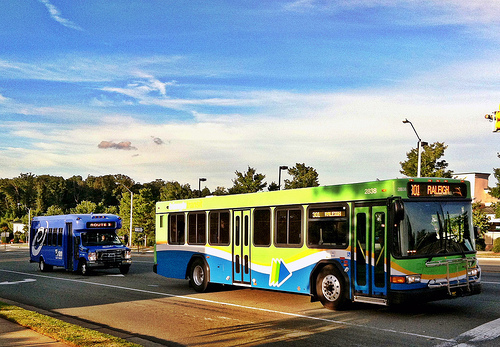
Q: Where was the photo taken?
A: It was taken at the street.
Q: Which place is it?
A: It is a street.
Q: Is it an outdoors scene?
A: Yes, it is outdoors.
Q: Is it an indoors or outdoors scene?
A: It is outdoors.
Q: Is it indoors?
A: No, it is outdoors.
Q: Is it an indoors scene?
A: No, it is outdoors.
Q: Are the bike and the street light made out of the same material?
A: Yes, both the bike and the street light are made of metal.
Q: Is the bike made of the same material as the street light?
A: Yes, both the bike and the street light are made of metal.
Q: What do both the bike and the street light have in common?
A: The material, both the bike and the street light are metallic.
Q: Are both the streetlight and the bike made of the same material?
A: Yes, both the streetlight and the bike are made of metal.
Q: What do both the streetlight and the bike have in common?
A: The material, both the streetlight and the bike are metallic.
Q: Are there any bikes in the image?
A: Yes, there is a bike.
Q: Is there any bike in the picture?
A: Yes, there is a bike.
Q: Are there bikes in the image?
A: Yes, there is a bike.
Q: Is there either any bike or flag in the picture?
A: Yes, there is a bike.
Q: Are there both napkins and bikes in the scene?
A: No, there is a bike but no napkins.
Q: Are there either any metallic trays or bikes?
A: Yes, there is a metal bike.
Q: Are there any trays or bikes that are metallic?
A: Yes, the bike is metallic.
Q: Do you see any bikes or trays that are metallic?
A: Yes, the bike is metallic.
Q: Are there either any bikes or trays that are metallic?
A: Yes, the bike is metallic.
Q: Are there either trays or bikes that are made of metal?
A: Yes, the bike is made of metal.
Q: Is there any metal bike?
A: Yes, there is a bike that is made of metal.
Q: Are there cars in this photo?
A: No, there are no cars.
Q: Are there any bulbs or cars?
A: No, there are no cars or bulbs.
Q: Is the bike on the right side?
A: Yes, the bike is on the right of the image.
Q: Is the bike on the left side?
A: No, the bike is on the right of the image.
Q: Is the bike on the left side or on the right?
A: The bike is on the right of the image.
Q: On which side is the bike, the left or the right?
A: The bike is on the right of the image.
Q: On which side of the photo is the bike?
A: The bike is on the right of the image.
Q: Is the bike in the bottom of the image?
A: Yes, the bike is in the bottom of the image.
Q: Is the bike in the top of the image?
A: No, the bike is in the bottom of the image.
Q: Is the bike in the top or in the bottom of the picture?
A: The bike is in the bottom of the image.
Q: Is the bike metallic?
A: Yes, the bike is metallic.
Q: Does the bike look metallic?
A: Yes, the bike is metallic.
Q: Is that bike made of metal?
A: Yes, the bike is made of metal.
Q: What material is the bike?
A: The bike is made of metal.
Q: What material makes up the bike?
A: The bike is made of metal.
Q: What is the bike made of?
A: The bike is made of metal.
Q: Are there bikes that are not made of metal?
A: No, there is a bike but it is made of metal.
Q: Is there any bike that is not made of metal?
A: No, there is a bike but it is made of metal.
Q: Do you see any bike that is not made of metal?
A: No, there is a bike but it is made of metal.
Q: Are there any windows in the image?
A: Yes, there is a window.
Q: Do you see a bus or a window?
A: Yes, there is a window.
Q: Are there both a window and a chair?
A: No, there is a window but no chairs.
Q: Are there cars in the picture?
A: No, there are no cars.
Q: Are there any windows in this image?
A: Yes, there is a window.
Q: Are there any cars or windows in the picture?
A: Yes, there is a window.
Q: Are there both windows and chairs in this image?
A: No, there is a window but no chairs.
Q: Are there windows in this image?
A: Yes, there is a window.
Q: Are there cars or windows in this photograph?
A: Yes, there is a window.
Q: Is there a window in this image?
A: Yes, there is a window.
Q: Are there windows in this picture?
A: Yes, there is a window.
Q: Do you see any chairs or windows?
A: Yes, there is a window.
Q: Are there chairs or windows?
A: Yes, there is a window.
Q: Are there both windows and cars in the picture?
A: No, there is a window but no cars.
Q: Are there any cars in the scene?
A: No, there are no cars.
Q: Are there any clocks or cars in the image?
A: No, there are no cars or clocks.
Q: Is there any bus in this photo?
A: Yes, there is a bus.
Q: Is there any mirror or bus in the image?
A: Yes, there is a bus.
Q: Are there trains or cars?
A: No, there are no cars or trains.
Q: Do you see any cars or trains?
A: No, there are no cars or trains.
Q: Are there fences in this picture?
A: No, there are no fences.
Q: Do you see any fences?
A: No, there are no fences.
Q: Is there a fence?
A: No, there are no fences.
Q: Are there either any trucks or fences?
A: No, there are no fences or trucks.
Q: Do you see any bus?
A: Yes, there is a bus.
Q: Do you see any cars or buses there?
A: Yes, there is a bus.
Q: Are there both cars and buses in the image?
A: No, there is a bus but no cars.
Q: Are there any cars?
A: No, there are no cars.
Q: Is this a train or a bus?
A: This is a bus.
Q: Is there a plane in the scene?
A: No, there are no airplanes.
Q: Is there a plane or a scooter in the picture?
A: No, there are no airplanes or scooters.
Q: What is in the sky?
A: The clouds are in the sky.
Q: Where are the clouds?
A: The clouds are in the sky.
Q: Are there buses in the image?
A: Yes, there is a bus.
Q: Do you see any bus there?
A: Yes, there is a bus.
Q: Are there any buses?
A: Yes, there is a bus.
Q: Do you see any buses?
A: Yes, there is a bus.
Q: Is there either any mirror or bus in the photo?
A: Yes, there is a bus.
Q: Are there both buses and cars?
A: No, there is a bus but no cars.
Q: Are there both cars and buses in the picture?
A: No, there is a bus but no cars.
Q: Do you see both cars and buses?
A: No, there is a bus but no cars.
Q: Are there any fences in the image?
A: No, there are no fences.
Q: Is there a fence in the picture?
A: No, there are no fences.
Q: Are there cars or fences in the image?
A: No, there are no fences or cars.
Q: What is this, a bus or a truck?
A: This is a bus.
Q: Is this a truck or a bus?
A: This is a bus.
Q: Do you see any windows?
A: Yes, there is a window.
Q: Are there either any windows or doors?
A: Yes, there is a window.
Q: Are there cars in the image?
A: No, there are no cars.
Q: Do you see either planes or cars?
A: No, there are no cars or planes.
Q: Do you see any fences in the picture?
A: No, there are no fences.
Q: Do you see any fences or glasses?
A: No, there are no fences or glasses.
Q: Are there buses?
A: Yes, there is a bus.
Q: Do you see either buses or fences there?
A: Yes, there is a bus.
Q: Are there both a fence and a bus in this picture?
A: No, there is a bus but no fences.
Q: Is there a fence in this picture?
A: No, there are no fences.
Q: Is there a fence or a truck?
A: No, there are no fences or trucks.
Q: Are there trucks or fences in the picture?
A: No, there are no fences or trucks.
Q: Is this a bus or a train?
A: This is a bus.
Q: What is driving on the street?
A: The bus is driving on the street.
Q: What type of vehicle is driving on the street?
A: The vehicle is a bus.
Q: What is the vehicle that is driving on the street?
A: The vehicle is a bus.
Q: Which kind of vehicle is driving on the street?
A: The vehicle is a bus.